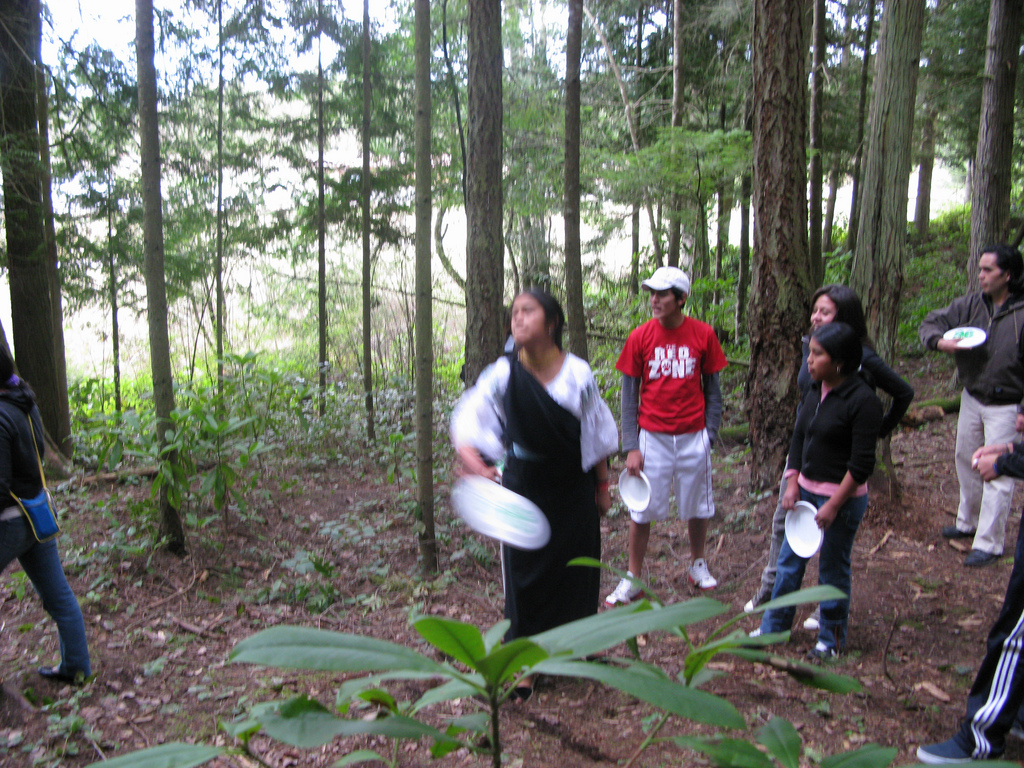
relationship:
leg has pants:
[955, 541, 1022, 751] [948, 574, 1021, 753]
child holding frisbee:
[742, 328, 883, 660] [772, 494, 827, 572]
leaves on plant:
[232, 598, 545, 723] [238, 554, 681, 758]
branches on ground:
[5, 350, 1021, 766] [4, 357, 1023, 766]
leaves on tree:
[325, 45, 430, 284] [715, 11, 807, 534]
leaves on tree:
[589, 95, 758, 219] [715, 11, 807, 534]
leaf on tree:
[716, 128, 751, 166] [299, 4, 339, 425]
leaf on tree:
[608, 149, 635, 165] [354, 10, 397, 450]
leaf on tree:
[522, 92, 549, 116] [190, 7, 260, 542]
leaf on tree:
[378, 220, 413, 252] [190, 7, 260, 542]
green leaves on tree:
[158, 48, 350, 212] [140, 1, 279, 438]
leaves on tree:
[58, 30, 160, 313] [39, 30, 175, 430]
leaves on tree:
[529, 623, 749, 735] [13, 43, 225, 468]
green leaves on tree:
[98, 89, 130, 143] [5, 36, 328, 354]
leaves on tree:
[525, 549, 856, 720] [52, 569, 992, 760]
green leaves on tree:
[74, 55, 136, 312] [55, 19, 147, 443]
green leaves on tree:
[317, 0, 371, 172] [258, 3, 414, 416]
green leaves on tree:
[595, 124, 748, 202] [602, 105, 740, 333]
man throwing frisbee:
[909, 234, 992, 572] [416, 466, 566, 574]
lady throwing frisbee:
[462, 264, 639, 666] [439, 472, 569, 561]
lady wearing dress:
[462, 264, 639, 666] [427, 344, 631, 626]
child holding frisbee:
[742, 328, 883, 660] [779, 496, 828, 561]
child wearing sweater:
[742, 328, 883, 660] [781, 370, 879, 491]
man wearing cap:
[607, 262, 725, 599] [642, 266, 691, 295]